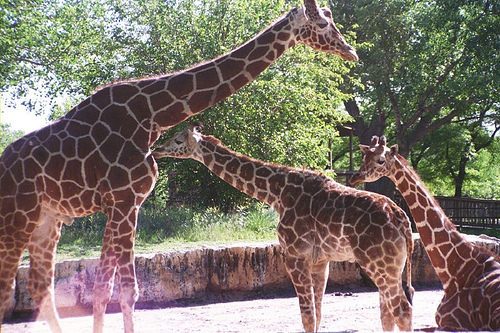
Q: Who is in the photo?
A: No one.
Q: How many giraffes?
A: Three.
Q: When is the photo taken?
A: Daytime.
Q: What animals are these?
A: Giraffe.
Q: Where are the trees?
A: Behind giraffes.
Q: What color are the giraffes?
A: Brown and yellow.